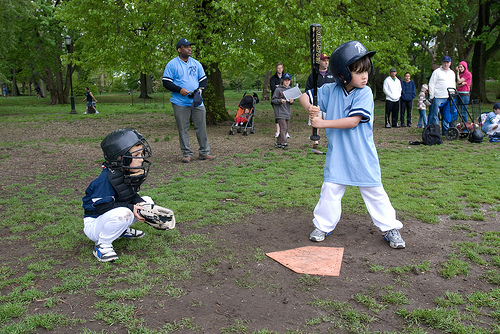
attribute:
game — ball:
[4, 7, 479, 331]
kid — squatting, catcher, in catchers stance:
[73, 141, 199, 250]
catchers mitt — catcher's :
[134, 197, 206, 238]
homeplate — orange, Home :
[272, 227, 353, 281]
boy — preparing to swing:
[313, 35, 410, 249]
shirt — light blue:
[311, 82, 385, 171]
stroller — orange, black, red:
[229, 88, 268, 141]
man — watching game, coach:
[156, 35, 219, 156]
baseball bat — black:
[302, 19, 330, 148]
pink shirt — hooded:
[456, 74, 475, 100]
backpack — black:
[428, 120, 438, 147]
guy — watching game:
[430, 56, 465, 122]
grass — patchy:
[187, 181, 299, 202]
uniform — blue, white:
[309, 87, 398, 231]